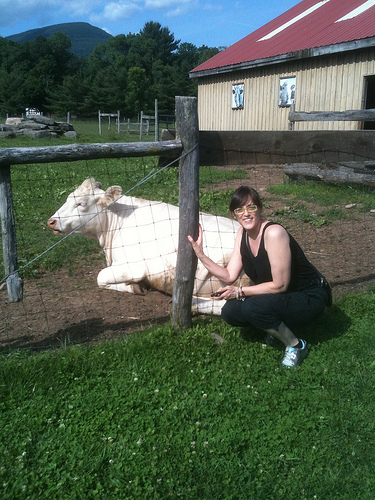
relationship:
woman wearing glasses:
[179, 173, 352, 373] [227, 204, 259, 220]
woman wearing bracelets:
[179, 173, 352, 373] [234, 281, 252, 304]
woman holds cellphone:
[179, 173, 352, 373] [210, 284, 230, 299]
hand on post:
[179, 217, 211, 262] [166, 90, 204, 333]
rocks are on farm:
[5, 108, 92, 147] [3, 3, 367, 491]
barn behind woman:
[153, 5, 374, 169] [179, 173, 352, 373]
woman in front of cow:
[179, 173, 352, 373] [38, 164, 251, 303]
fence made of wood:
[11, 94, 214, 351] [152, 139, 184, 154]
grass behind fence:
[12, 142, 214, 261] [11, 94, 214, 351]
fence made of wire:
[11, 94, 214, 351] [20, 172, 113, 254]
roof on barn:
[182, 10, 374, 87] [153, 5, 374, 169]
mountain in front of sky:
[1, 17, 124, 55] [1, 4, 291, 53]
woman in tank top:
[179, 173, 352, 373] [232, 222, 324, 297]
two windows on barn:
[226, 69, 315, 117] [153, 5, 374, 169]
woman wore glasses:
[179, 173, 352, 373] [227, 204, 259, 220]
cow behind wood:
[38, 164, 251, 303] [152, 139, 184, 154]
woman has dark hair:
[179, 173, 352, 373] [233, 186, 259, 200]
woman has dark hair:
[179, 173, 352, 373] [224, 186, 271, 216]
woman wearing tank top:
[179, 173, 352, 373] [232, 222, 324, 297]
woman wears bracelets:
[179, 173, 352, 373] [234, 281, 252, 304]